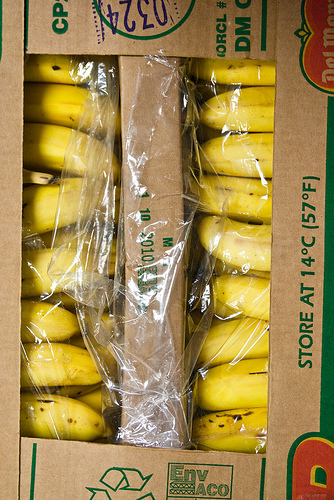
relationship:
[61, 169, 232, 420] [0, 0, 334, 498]
bananas in box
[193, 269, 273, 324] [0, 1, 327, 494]
banana in box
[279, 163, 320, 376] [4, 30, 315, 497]
instructions on box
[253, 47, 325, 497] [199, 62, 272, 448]
box has bananas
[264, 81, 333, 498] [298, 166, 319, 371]
box has lettering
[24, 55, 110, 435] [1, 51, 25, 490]
bananas in box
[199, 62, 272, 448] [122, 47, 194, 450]
bananas in box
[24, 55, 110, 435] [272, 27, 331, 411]
bananas in box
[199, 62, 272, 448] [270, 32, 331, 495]
bananas in box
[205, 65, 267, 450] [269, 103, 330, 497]
bananas in box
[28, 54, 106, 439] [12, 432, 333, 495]
bananas in box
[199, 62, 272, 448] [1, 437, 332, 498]
bananas in box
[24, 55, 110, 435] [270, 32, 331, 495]
bananas in box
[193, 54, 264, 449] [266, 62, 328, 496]
bananas in box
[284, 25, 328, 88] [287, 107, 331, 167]
logo on box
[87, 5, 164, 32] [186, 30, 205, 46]
numbers on box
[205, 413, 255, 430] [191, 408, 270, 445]
spot on banana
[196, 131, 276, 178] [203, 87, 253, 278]
banana on banana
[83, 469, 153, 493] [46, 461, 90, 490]
sign on box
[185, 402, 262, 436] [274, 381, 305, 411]
banana in box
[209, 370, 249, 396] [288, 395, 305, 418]
banana in box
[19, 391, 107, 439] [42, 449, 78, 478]
bananas in box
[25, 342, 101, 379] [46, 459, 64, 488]
banana in box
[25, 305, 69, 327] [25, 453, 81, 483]
banana in box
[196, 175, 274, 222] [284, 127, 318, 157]
bananas in box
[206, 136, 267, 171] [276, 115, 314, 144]
banana in box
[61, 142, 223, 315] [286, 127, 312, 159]
bananas in box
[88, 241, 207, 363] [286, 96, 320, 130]
wrap in box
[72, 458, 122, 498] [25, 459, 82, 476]
symbol on box